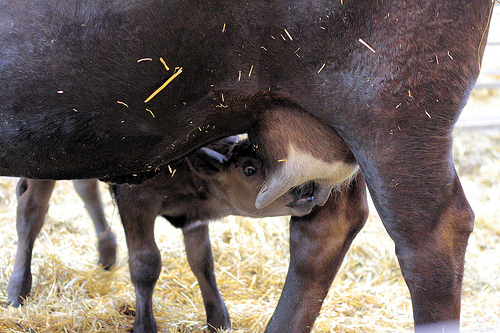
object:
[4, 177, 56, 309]
leg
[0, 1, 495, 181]
body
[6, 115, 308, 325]
dog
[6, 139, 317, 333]
calf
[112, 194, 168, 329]
leg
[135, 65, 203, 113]
straw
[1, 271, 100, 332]
hay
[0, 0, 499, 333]
cow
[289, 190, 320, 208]
teeth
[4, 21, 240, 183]
belly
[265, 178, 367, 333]
legs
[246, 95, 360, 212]
udders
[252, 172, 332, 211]
teats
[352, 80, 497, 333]
leg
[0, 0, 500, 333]
photo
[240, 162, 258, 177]
eye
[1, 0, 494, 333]
mom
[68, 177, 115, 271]
legs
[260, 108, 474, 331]
feet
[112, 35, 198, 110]
hay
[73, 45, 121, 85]
fur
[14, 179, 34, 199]
opening